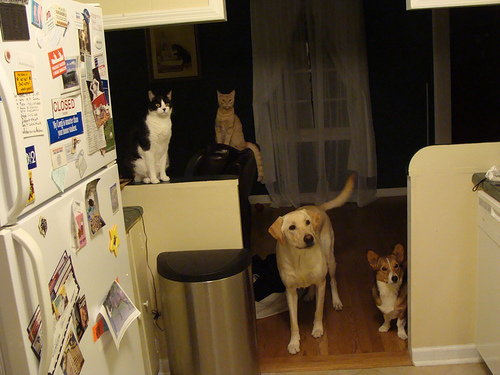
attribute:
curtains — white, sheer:
[251, 0, 375, 205]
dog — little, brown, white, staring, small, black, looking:
[367, 244, 409, 338]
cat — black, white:
[123, 88, 176, 184]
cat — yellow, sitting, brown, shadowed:
[213, 89, 263, 184]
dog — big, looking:
[267, 170, 355, 355]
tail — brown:
[322, 174, 357, 209]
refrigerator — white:
[0, 4, 146, 374]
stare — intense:
[381, 265, 400, 274]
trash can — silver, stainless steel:
[158, 248, 258, 373]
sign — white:
[51, 99, 76, 119]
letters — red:
[52, 99, 77, 112]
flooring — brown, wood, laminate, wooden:
[251, 194, 487, 373]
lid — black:
[156, 249, 252, 284]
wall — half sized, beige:
[409, 144, 499, 365]